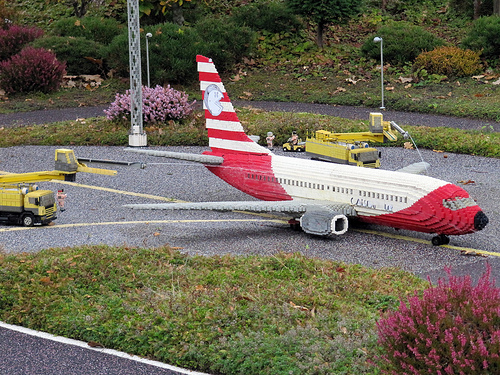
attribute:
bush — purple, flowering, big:
[376, 259, 500, 374]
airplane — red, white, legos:
[125, 53, 488, 249]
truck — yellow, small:
[303, 111, 406, 172]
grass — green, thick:
[1, 108, 500, 157]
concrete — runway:
[2, 99, 500, 293]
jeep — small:
[281, 141, 306, 153]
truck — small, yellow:
[2, 149, 118, 229]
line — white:
[1, 323, 212, 374]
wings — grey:
[120, 145, 431, 233]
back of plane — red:
[123, 50, 291, 202]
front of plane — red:
[384, 178, 489, 245]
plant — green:
[1, 0, 496, 91]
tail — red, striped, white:
[194, 53, 277, 156]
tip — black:
[476, 210, 488, 232]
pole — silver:
[124, 1, 149, 148]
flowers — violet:
[402, 292, 467, 353]